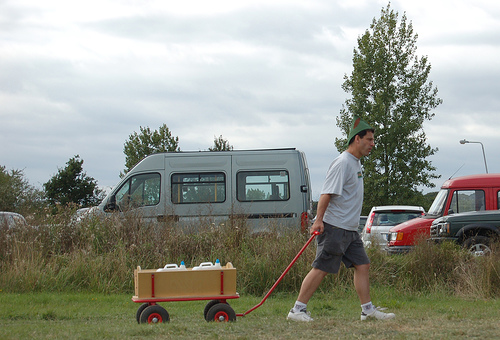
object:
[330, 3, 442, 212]
tree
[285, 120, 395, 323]
man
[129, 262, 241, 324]
wagon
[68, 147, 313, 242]
van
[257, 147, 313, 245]
back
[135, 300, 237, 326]
wheels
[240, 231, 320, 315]
pole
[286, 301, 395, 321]
shoes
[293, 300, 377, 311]
socks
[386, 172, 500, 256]
red vehicle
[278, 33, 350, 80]
clouds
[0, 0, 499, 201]
sky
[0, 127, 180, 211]
trees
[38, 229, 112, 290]
grasses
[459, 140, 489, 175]
street light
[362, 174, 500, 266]
vehicles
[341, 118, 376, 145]
hat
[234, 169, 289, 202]
window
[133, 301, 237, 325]
tires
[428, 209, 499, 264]
black car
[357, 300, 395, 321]
left foot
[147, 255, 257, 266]
containers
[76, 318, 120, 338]
road